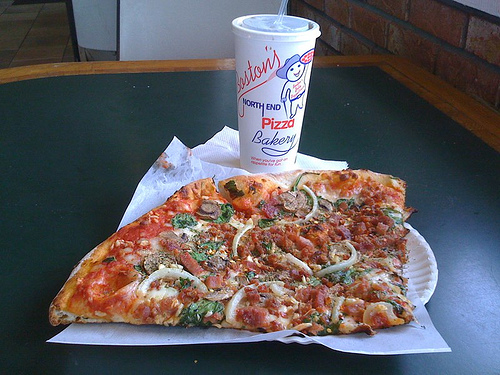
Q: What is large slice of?
A: Pizza.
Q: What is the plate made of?
A: Paper.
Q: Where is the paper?
A: Under pizza.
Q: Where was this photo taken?
A: In a restaurant.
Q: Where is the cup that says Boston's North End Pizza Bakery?
A: On the table.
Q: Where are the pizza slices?
A: On a white plate.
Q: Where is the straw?
A: In the to-go cup.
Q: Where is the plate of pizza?
A: On the table.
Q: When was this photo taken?
A: During the daytime.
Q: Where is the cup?
A: Sitting on the table.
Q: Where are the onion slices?
A: On top of the pizza.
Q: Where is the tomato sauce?
A: On the pizza.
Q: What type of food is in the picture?
A: Pizza.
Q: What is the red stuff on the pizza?
A: Sauce.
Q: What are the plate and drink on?
A: Table.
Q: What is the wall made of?
A: Red bricks.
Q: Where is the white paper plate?
A: Under the slices of pizza.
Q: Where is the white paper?
A: Between the pizza and the plate.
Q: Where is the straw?
A: In the drink.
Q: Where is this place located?
A: Pizza place.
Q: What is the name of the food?
A: A pizza.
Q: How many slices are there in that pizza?
A: Two slices.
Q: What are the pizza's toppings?
A: Onions, mushrooms, beef, cheese and basil.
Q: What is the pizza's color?
A: It's red.